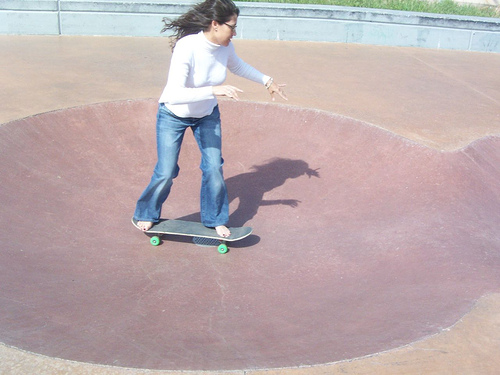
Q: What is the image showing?
A: It is showing a skate park.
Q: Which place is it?
A: It is a skate park.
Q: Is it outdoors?
A: Yes, it is outdoors.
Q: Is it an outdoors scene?
A: Yes, it is outdoors.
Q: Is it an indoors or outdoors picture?
A: It is outdoors.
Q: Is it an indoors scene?
A: No, it is outdoors.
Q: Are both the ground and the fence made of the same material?
A: Yes, both the ground and the fence are made of concrete.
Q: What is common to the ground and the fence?
A: The material, both the ground and the fence are concrete.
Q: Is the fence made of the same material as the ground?
A: Yes, both the fence and the ground are made of cement.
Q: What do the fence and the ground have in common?
A: The material, both the fence and the ground are concrete.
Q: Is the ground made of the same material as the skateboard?
A: No, the ground is made of cement and the skateboard is made of wood.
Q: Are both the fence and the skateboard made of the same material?
A: No, the fence is made of concrete and the skateboard is made of wood.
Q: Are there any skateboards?
A: Yes, there is a skateboard.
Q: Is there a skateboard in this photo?
A: Yes, there is a skateboard.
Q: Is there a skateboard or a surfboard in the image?
A: Yes, there is a skateboard.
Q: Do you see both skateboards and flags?
A: No, there is a skateboard but no flags.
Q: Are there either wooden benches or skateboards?
A: Yes, there is a wood skateboard.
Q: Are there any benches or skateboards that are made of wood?
A: Yes, the skateboard is made of wood.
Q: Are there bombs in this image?
A: No, there are no bombs.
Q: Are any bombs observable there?
A: No, there are no bombs.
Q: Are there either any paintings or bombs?
A: No, there are no bombs or paintings.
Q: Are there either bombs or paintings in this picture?
A: No, there are no bombs or paintings.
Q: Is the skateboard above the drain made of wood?
A: Yes, the skateboard is made of wood.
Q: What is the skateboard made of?
A: The skateboard is made of wood.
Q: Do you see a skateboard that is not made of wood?
A: No, there is a skateboard but it is made of wood.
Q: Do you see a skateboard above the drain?
A: Yes, there is a skateboard above the drain.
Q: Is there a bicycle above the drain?
A: No, there is a skateboard above the drain.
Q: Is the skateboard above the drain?
A: Yes, the skateboard is above the drain.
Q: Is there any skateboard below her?
A: Yes, there is a skateboard below the woman.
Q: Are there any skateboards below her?
A: Yes, there is a skateboard below the woman.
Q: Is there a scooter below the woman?
A: No, there is a skateboard below the woman.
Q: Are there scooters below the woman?
A: No, there is a skateboard below the woman.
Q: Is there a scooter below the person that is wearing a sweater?
A: No, there is a skateboard below the woman.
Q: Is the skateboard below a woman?
A: Yes, the skateboard is below a woman.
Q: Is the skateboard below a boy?
A: No, the skateboard is below a woman.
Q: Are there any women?
A: Yes, there is a woman.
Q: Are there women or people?
A: Yes, there is a woman.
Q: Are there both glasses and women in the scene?
A: Yes, there are both a woman and glasses.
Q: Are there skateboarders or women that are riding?
A: Yes, the woman is riding.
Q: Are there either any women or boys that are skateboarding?
A: Yes, the woman is skateboarding.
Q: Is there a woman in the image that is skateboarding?
A: Yes, there is a woman that is skateboarding.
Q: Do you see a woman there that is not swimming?
A: Yes, there is a woman that is skateboarding .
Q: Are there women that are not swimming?
A: Yes, there is a woman that is skateboarding.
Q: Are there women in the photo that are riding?
A: Yes, there is a woman that is riding.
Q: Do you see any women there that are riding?
A: Yes, there is a woman that is riding.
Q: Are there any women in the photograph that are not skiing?
A: Yes, there is a woman that is riding.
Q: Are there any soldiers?
A: No, there are no soldiers.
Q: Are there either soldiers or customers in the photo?
A: No, there are no soldiers or customers.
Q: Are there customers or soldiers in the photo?
A: No, there are no soldiers or customers.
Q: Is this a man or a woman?
A: This is a woman.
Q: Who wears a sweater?
A: The woman wears a sweater.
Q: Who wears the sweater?
A: The woman wears a sweater.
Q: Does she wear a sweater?
A: Yes, the woman wears a sweater.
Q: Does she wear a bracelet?
A: No, the woman wears a sweater.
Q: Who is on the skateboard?
A: The woman is on the skateboard.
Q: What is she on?
A: The woman is on the skateboard.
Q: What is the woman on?
A: The woman is on the skateboard.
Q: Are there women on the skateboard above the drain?
A: Yes, there is a woman on the skateboard.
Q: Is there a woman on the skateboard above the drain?
A: Yes, there is a woman on the skateboard.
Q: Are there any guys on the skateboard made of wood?
A: No, there is a woman on the skateboard.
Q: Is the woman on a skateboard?
A: Yes, the woman is on a skateboard.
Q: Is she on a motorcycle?
A: No, the woman is on a skateboard.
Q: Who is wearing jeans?
A: The woman is wearing jeans.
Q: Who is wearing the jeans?
A: The woman is wearing jeans.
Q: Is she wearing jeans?
A: Yes, the woman is wearing jeans.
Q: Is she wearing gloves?
A: No, the woman is wearing jeans.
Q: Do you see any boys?
A: No, there are no boys.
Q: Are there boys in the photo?
A: No, there are no boys.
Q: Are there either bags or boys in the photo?
A: No, there are no boys or bags.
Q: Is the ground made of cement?
A: Yes, the ground is made of cement.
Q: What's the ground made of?
A: The ground is made of concrete.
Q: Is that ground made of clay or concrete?
A: The ground is made of concrete.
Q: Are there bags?
A: No, there are no bags.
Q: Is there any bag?
A: No, there are no bags.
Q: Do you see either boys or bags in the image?
A: No, there are no bags or boys.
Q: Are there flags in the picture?
A: No, there are no flags.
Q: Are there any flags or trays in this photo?
A: No, there are no flags or trays.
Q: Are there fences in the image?
A: Yes, there is a fence.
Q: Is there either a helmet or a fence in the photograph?
A: Yes, there is a fence.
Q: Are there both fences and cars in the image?
A: No, there is a fence but no cars.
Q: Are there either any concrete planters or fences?
A: Yes, there is a concrete fence.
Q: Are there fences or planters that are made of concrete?
A: Yes, the fence is made of concrete.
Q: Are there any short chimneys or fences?
A: Yes, there is a short fence.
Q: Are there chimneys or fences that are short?
A: Yes, the fence is short.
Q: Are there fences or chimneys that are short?
A: Yes, the fence is short.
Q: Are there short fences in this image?
A: Yes, there is a short fence.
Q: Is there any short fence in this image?
A: Yes, there is a short fence.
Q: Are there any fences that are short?
A: Yes, there is a fence that is short.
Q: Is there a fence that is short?
A: Yes, there is a fence that is short.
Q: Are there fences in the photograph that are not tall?
A: Yes, there is a short fence.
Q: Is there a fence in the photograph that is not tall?
A: Yes, there is a short fence.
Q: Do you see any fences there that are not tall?
A: Yes, there is a short fence.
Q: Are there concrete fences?
A: Yes, there is a fence that is made of concrete.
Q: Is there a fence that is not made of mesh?
A: Yes, there is a fence that is made of cement.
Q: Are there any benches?
A: No, there are no benches.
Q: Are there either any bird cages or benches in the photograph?
A: No, there are no benches or bird cages.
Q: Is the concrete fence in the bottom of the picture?
A: No, the fence is in the top of the image.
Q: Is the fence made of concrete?
A: Yes, the fence is made of concrete.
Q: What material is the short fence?
A: The fence is made of cement.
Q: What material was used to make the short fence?
A: The fence is made of cement.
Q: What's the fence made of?
A: The fence is made of concrete.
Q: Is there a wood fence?
A: No, there is a fence but it is made of cement.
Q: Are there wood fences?
A: No, there is a fence but it is made of cement.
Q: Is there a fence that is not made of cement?
A: No, there is a fence but it is made of cement.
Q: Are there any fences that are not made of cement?
A: No, there is a fence but it is made of cement.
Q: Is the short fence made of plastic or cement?
A: The fence is made of cement.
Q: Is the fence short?
A: Yes, the fence is short.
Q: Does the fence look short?
A: Yes, the fence is short.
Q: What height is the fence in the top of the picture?
A: The fence is short.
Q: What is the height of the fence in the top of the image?
A: The fence is short.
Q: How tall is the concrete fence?
A: The fence is short.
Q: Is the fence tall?
A: No, the fence is short.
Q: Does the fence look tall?
A: No, the fence is short.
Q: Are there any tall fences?
A: No, there is a fence but it is short.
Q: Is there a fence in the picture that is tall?
A: No, there is a fence but it is short.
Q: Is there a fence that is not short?
A: No, there is a fence but it is short.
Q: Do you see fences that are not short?
A: No, there is a fence but it is short.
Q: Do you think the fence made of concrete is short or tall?
A: The fence is short.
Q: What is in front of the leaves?
A: The fence is in front of the leaves.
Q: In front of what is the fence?
A: The fence is in front of the leaves.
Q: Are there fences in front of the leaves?
A: Yes, there is a fence in front of the leaves.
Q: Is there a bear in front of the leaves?
A: No, there is a fence in front of the leaves.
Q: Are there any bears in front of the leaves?
A: No, there is a fence in front of the leaves.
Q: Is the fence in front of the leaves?
A: Yes, the fence is in front of the leaves.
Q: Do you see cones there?
A: No, there are no cones.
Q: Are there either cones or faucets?
A: No, there are no cones or faucets.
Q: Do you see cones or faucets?
A: No, there are no cones or faucets.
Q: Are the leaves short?
A: Yes, the leaves are short.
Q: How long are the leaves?
A: The leaves are short.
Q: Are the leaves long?
A: No, the leaves are short.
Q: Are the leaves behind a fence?
A: Yes, the leaves are behind a fence.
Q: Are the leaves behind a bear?
A: No, the leaves are behind a fence.